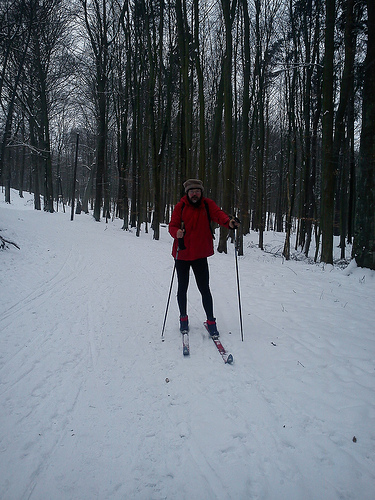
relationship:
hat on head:
[182, 177, 203, 192] [181, 176, 207, 206]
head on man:
[181, 176, 207, 206] [161, 177, 236, 334]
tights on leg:
[174, 257, 214, 319] [192, 262, 213, 317]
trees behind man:
[0, 0, 373, 271] [161, 177, 236, 334]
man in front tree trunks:
[161, 177, 236, 334] [0, 90, 375, 264]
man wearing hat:
[161, 177, 236, 334] [182, 181, 199, 190]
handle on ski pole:
[177, 222, 185, 246] [155, 219, 192, 341]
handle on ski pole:
[229, 216, 242, 239] [229, 212, 253, 345]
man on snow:
[161, 177, 236, 334] [1, 184, 372, 499]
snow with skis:
[1, 184, 372, 499] [175, 325, 233, 364]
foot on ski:
[206, 318, 222, 337] [201, 318, 234, 365]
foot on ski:
[175, 314, 189, 333] [179, 311, 189, 355]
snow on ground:
[1, 184, 372, 499] [0, 182, 373, 497]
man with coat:
[161, 177, 236, 334] [169, 195, 229, 258]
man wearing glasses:
[161, 177, 236, 334] [186, 189, 203, 194]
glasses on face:
[186, 189, 203, 194] [186, 185, 201, 205]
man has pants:
[161, 177, 236, 334] [171, 253, 215, 323]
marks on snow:
[0, 242, 98, 499] [1, 184, 372, 499]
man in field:
[161, 177, 236, 334] [4, 185, 374, 498]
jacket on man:
[169, 193, 232, 259] [161, 177, 236, 334]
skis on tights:
[177, 317, 235, 363] [174, 257, 214, 319]